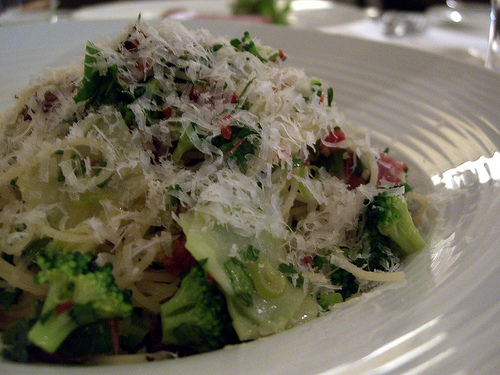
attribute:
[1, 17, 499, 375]
plate — round, white, full, large, ridged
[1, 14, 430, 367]
food — salad, white, yummy, creamy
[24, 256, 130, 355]
broccoli — green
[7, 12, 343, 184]
shreddings — white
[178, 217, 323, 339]
lettuce — big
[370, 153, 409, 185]
tomato — red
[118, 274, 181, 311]
noodles — small